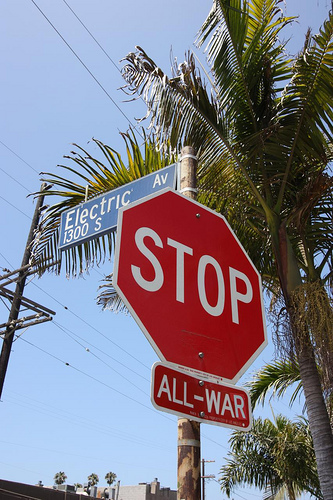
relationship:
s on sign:
[128, 223, 172, 297] [110, 194, 258, 373]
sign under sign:
[161, 363, 253, 419] [110, 194, 258, 373]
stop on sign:
[120, 224, 257, 333] [110, 194, 258, 373]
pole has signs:
[177, 153, 206, 499] [78, 148, 252, 421]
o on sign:
[192, 243, 227, 320] [110, 194, 258, 373]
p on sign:
[227, 266, 257, 327] [110, 194, 258, 373]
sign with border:
[110, 194, 258, 373] [109, 207, 126, 285]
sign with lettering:
[110, 194, 258, 373] [120, 231, 258, 317]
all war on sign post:
[157, 372, 254, 418] [177, 153, 206, 499]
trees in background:
[211, 17, 329, 493] [2, 9, 331, 470]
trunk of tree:
[277, 284, 331, 432] [204, 2, 331, 500]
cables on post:
[32, 310, 146, 414] [4, 175, 44, 355]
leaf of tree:
[263, 364, 288, 382] [204, 2, 331, 500]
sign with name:
[110, 194, 258, 373] [62, 181, 134, 220]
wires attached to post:
[44, 5, 157, 129] [4, 175, 44, 355]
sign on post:
[110, 194, 258, 373] [174, 144, 193, 495]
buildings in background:
[0, 462, 197, 499] [2, 9, 331, 470]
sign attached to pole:
[110, 194, 258, 373] [177, 153, 206, 499]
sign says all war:
[161, 363, 253, 419] [157, 372, 254, 418]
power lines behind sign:
[65, 318, 143, 381] [161, 363, 253, 419]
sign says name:
[47, 175, 193, 236] [62, 181, 134, 220]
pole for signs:
[177, 153, 206, 499] [78, 148, 252, 421]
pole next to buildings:
[2, 172, 51, 392] [0, 462, 197, 499]